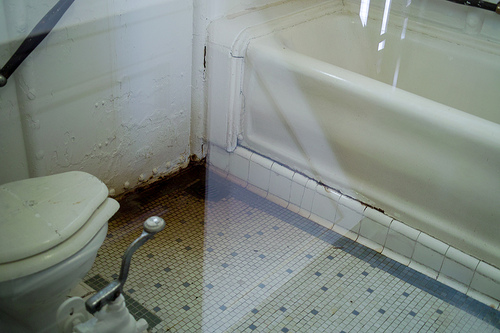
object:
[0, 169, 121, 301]
seat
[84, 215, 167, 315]
lever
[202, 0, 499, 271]
bathtub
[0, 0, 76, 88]
bar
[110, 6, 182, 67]
wall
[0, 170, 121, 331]
toilet seat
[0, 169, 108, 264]
cover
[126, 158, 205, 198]
rust stain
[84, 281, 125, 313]
light reflection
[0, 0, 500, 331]
bathroom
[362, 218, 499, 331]
tiles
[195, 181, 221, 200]
drain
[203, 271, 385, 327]
floor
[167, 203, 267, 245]
stain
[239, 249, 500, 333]
tile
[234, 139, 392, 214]
crack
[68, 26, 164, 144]
paint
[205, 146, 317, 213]
tile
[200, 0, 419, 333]
reflection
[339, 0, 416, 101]
window glass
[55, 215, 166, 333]
foot pedal